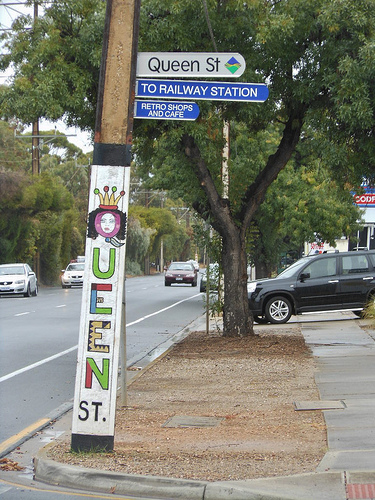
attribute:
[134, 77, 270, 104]
street sign — blue, white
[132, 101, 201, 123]
street sign — blue, white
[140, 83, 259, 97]
lettering — white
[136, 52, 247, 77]
sign — white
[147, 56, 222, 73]
lettering — black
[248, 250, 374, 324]
suv — black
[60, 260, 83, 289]
car — white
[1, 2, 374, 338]
tree — large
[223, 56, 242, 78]
diamond shape — green, blue, colorful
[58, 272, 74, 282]
headlight — on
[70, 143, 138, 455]
white sign — painted, tall, vertical, black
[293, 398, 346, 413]
square — concrete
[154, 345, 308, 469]
dirt — light brown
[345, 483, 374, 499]
brick pathway — red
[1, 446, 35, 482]
leaves — dead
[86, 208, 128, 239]
hair — black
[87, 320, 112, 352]
letter e — yellow, black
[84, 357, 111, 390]
letter n — pink, painted, green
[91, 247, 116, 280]
letter u — painted, solid green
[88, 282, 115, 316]
letter e — red, painted, green, blue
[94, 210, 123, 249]
letter q — painted, purple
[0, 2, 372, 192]
leaves — bright green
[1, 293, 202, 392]
line — white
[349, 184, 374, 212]
sign — red, blue, white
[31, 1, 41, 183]
electrical pole — wood